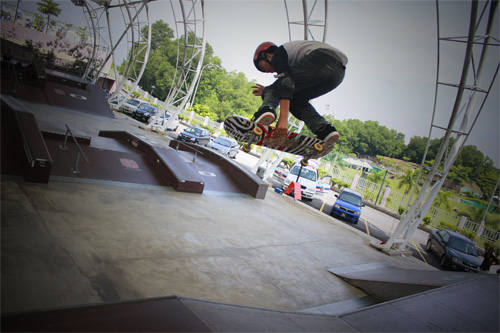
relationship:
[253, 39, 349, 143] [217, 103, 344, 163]
boy holding skate board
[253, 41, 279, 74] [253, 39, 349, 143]
helmet on boy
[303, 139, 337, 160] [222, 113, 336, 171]
tires on skateboard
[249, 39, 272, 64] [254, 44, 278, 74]
helmet on head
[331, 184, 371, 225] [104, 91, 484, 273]
car in lot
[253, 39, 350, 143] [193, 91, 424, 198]
boy on skateboard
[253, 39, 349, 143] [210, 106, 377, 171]
boy on skateboard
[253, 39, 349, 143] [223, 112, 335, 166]
boy on skateboard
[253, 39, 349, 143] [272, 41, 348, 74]
boy on t-shirt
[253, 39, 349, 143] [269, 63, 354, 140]
boy on black pants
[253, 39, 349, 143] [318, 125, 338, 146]
boy on shoe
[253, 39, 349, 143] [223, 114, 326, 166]
boy on skateboard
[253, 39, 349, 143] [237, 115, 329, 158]
boy on skateboard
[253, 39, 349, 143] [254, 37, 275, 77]
boy wearing helmet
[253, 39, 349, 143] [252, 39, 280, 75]
boy wearing helmet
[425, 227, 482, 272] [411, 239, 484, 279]
car parked in spot